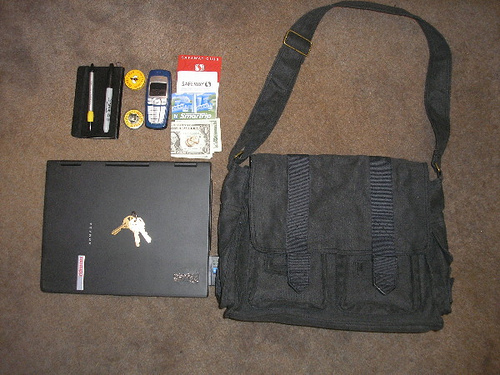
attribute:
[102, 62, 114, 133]
marker — part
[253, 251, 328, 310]
pocket — part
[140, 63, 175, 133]
cell phone — blue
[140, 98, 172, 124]
button — white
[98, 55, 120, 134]
sharpie — black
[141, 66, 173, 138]
cellphone — silver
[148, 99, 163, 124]
button — white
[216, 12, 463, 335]
bag — part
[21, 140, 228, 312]
laptop — part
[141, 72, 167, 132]
phone — cell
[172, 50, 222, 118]
ticket — plane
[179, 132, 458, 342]
laptop satchel — black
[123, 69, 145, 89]
circle — yellow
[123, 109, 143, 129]
circle — yellow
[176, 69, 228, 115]
receipt — white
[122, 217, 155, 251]
keys — shiny, metal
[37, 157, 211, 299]
laptop — black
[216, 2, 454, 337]
laptop bag — black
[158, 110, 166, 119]
button — white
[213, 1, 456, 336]
black bag — computer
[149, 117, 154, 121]
botton — white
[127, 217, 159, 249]
keys — silver, ring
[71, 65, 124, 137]
notebook — part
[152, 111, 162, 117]
button — white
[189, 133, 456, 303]
bag — black, computer, strap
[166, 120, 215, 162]
dollar bill — folded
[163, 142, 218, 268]
laptop — closed, black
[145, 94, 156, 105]
button — white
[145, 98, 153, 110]
button — white